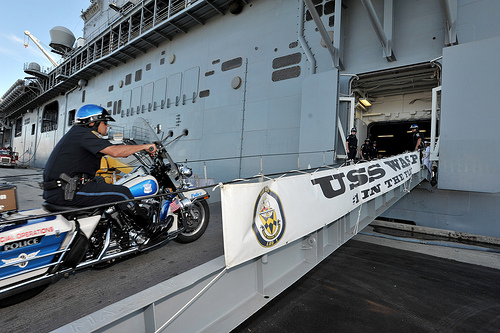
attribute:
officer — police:
[40, 102, 133, 220]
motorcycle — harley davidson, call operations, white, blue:
[7, 148, 225, 276]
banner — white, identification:
[216, 166, 427, 257]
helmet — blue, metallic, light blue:
[74, 101, 110, 124]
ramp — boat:
[191, 159, 422, 333]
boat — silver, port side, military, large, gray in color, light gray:
[7, 10, 500, 203]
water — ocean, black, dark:
[376, 229, 494, 256]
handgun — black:
[58, 171, 80, 203]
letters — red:
[0, 227, 60, 246]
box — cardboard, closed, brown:
[1, 184, 20, 212]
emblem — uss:
[243, 187, 291, 250]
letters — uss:
[314, 168, 396, 199]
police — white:
[4, 238, 39, 251]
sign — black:
[2, 234, 41, 254]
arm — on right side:
[94, 137, 157, 159]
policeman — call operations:
[34, 99, 175, 235]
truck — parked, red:
[1, 147, 18, 170]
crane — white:
[19, 29, 57, 74]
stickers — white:
[0, 194, 7, 211]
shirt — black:
[41, 123, 107, 178]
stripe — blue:
[78, 189, 126, 201]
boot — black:
[141, 214, 179, 243]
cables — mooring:
[14, 134, 51, 171]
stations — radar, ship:
[44, 28, 78, 53]